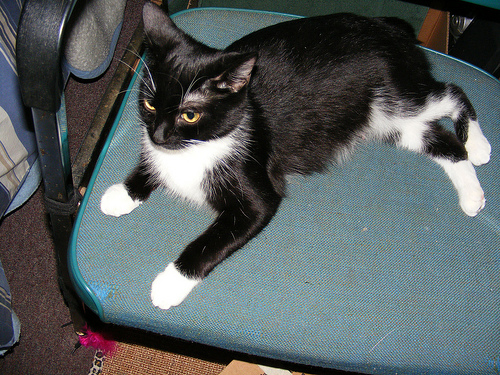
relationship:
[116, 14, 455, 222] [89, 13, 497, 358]
cat on seat